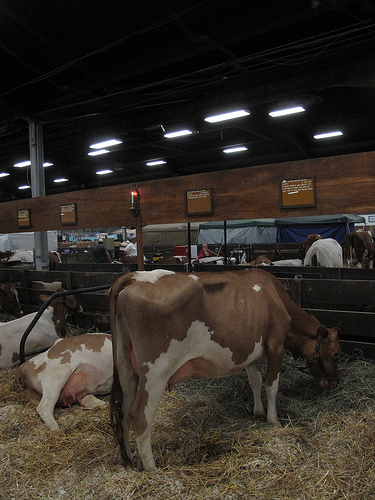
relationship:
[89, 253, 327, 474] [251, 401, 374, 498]
cow sitting on hay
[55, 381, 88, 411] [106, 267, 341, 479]
udder under cow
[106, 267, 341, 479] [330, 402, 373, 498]
cow eating hay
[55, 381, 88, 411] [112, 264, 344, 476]
udder on cow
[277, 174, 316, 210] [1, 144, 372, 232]
sign hangs on wall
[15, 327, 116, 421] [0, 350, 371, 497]
cow laying on hay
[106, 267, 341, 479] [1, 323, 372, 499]
cow eating hay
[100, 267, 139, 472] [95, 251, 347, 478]
tail on cow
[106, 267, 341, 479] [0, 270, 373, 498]
cow in stall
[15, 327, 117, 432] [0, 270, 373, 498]
cow in stall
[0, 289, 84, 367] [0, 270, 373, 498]
cow in stall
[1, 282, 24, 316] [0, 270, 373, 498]
cow in stall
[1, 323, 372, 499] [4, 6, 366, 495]
hay in stall